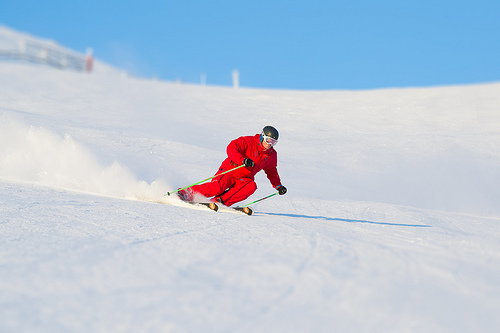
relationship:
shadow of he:
[255, 210, 430, 228] [174, 125, 286, 207]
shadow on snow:
[255, 210, 430, 228] [0, 198, 500, 330]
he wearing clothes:
[174, 125, 286, 207] [178, 135, 281, 212]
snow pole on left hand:
[243, 190, 288, 208] [276, 184, 291, 196]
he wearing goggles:
[174, 125, 286, 207] [261, 127, 278, 154]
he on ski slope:
[174, 125, 286, 207] [2, 60, 497, 331]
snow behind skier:
[10, 124, 176, 197] [181, 126, 295, 215]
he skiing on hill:
[166, 127, 286, 216] [0, 59, 499, 332]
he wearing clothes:
[174, 125, 286, 207] [210, 132, 282, 191]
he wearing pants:
[174, 125, 286, 207] [188, 167, 283, 224]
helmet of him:
[265, 124, 282, 141] [166, 123, 286, 214]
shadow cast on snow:
[253, 208, 434, 227] [87, 212, 222, 306]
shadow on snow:
[253, 208, 434, 227] [87, 212, 222, 306]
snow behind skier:
[2, 55, 496, 332] [170, 122, 285, 209]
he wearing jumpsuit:
[174, 125, 286, 207] [197, 132, 277, 201]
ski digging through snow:
[183, 200, 219, 212] [168, 188, 264, 218]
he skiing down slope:
[174, 125, 286, 207] [303, 65, 466, 285]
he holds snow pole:
[174, 125, 286, 207] [235, 191, 279, 208]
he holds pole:
[174, 125, 286, 207] [158, 162, 253, 197]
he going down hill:
[174, 125, 286, 207] [134, 60, 470, 303]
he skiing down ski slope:
[174, 125, 286, 207] [0, 63, 499, 333]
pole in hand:
[197, 154, 267, 192] [241, 147, 258, 170]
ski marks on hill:
[48, 208, 356, 328] [3, 55, 498, 325]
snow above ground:
[0, 198, 500, 330] [13, 84, 496, 330]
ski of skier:
[232, 202, 251, 214] [178, 121, 287, 200]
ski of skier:
[165, 188, 219, 210] [178, 121, 287, 200]